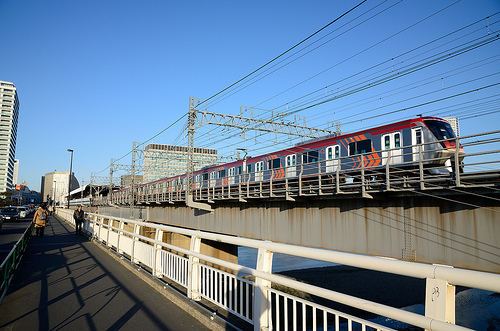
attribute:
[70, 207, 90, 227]
clothing — black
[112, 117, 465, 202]
train — red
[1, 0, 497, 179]
sky — blue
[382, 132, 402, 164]
doors — white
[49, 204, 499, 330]
rail — white